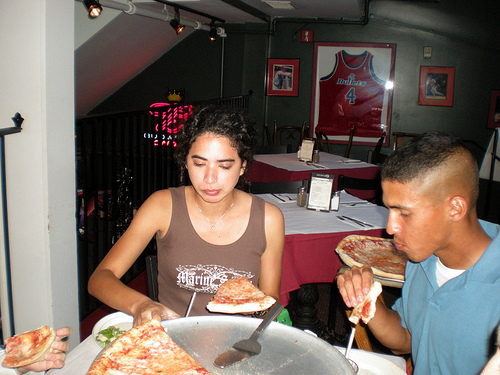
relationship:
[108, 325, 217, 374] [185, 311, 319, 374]
pizza on tray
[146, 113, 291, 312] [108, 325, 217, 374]
girl holding pizza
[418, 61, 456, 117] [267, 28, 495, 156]
picture on wall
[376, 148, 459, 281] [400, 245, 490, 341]
guy wearing shirt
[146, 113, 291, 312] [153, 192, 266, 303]
girl wearing top